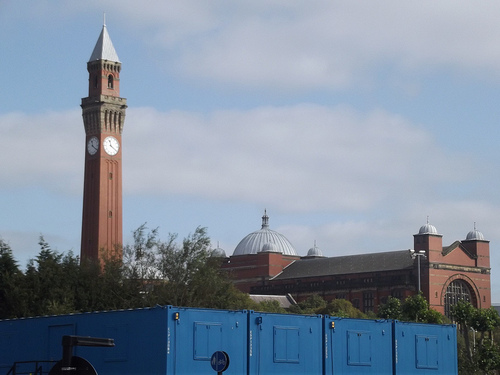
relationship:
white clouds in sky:
[158, 97, 217, 189] [14, 10, 488, 304]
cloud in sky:
[0, 0, 500, 272] [14, 10, 488, 304]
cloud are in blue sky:
[0, 0, 500, 272] [0, 0, 499, 304]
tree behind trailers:
[308, 292, 365, 318] [2, 297, 458, 374]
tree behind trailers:
[381, 287, 451, 325] [2, 297, 458, 374]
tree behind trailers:
[97, 234, 238, 312] [2, 297, 458, 374]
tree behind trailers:
[2, 238, 115, 317] [2, 297, 458, 374]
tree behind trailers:
[443, 289, 497, 372] [2, 297, 458, 374]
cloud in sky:
[0, 0, 500, 272] [150, 45, 450, 199]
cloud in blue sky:
[0, 0, 500, 272] [0, 0, 499, 304]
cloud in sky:
[0, 0, 500, 272] [247, 104, 439, 252]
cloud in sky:
[0, 0, 500, 272] [145, 81, 232, 115]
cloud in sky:
[0, 0, 500, 272] [130, 3, 498, 204]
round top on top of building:
[230, 203, 297, 255] [197, 248, 365, 294]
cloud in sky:
[283, 32, 368, 82] [14, 10, 488, 304]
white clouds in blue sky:
[1, 0, 498, 302] [0, 0, 499, 304]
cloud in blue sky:
[0, 0, 500, 272] [3, 12, 83, 104]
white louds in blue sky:
[165, 102, 498, 210] [0, 0, 499, 304]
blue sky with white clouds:
[0, 0, 499, 304] [185, 0, 498, 100]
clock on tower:
[83, 131, 98, 157] [75, 10, 130, 271]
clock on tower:
[97, 132, 120, 158] [75, 10, 130, 271]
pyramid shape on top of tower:
[88, 25, 122, 62] [75, 10, 130, 271]